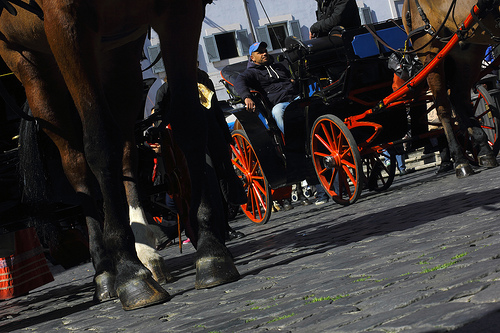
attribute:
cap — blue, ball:
[245, 39, 270, 54]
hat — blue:
[244, 40, 267, 52]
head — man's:
[248, 40, 270, 63]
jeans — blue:
[265, 95, 300, 145]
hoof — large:
[182, 219, 244, 296]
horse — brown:
[402, 2, 498, 179]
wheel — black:
[309, 116, 361, 207]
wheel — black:
[470, 82, 497, 149]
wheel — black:
[237, 126, 272, 223]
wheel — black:
[371, 149, 396, 188]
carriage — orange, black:
[225, 10, 421, 222]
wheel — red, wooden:
[261, 106, 411, 213]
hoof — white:
[130, 206, 167, 283]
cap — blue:
[241, 35, 271, 55]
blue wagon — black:
[217, 19, 407, 227]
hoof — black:
[88, 265, 130, 307]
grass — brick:
[308, 292, 344, 302]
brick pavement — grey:
[0, 166, 498, 331]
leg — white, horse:
[117, 149, 174, 290]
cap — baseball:
[248, 39, 267, 57]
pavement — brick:
[7, 143, 497, 331]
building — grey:
[127, 2, 423, 135]